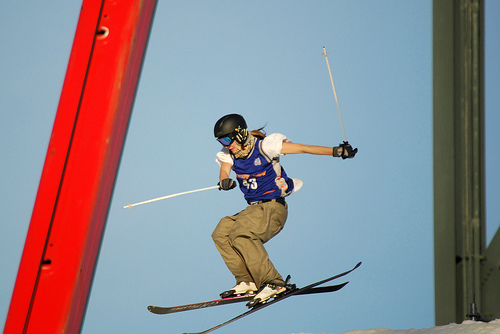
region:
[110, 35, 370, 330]
woman is jumping on skis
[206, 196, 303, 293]
skier is wearing brown ski pants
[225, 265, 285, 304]
skier has white ski boots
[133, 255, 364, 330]
a pair of skis attached to the skier's feet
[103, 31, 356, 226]
skier is carrying two white poles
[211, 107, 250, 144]
skier is wearing a black helmet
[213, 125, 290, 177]
skier is wearing a white shirt under a blue jersey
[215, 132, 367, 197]
skier is wearing black gloves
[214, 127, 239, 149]
skier is wearing goggles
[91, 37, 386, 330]
A professional skier in mid air after a jump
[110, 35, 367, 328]
A professional skier in mid air after a jump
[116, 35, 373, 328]
A professional skier in mid air after a jump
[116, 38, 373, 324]
A professional skier in mid air after a jump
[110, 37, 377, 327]
A professional skier in mid air after a jump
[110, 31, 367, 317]
A professional skier in mid air after a jump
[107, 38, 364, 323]
A professional skier in mid air after a jump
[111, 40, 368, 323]
A professional skier in mid air after a jump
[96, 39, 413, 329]
skier in the air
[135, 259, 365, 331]
a pair of skis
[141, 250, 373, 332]
skis attached to the feet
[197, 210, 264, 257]
knees are bent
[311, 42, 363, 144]
ski pole is upside down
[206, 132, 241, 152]
large goggles on the face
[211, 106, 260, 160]
black helmet on the head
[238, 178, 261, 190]
white numbers on the stomach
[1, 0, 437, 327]
blue sky with no clouds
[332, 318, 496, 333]
white snow on the ground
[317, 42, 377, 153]
this is a pole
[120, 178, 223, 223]
this is a pole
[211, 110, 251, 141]
this is a helmet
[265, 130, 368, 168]
this is a hand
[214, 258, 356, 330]
this is a ski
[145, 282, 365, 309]
this is a ski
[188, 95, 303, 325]
this is a person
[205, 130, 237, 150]
this is a pair of goggles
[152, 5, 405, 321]
this is clear sky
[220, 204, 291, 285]
this is a pair of trousers